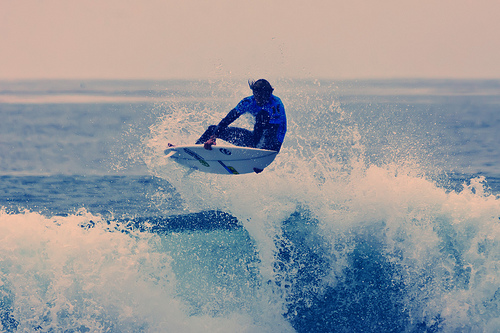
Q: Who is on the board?
A: A man.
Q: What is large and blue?
A: The wave.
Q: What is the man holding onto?
A: A surfboard.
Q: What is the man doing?
A: Surfing.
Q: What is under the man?
A: A surfboard.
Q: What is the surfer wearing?
A: A wet suit.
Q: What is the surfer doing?
A: Riding the waves.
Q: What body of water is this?
A: The ocean.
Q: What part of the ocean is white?
A: The waves.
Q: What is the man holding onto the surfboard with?
A: Two hands.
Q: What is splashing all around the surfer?
A: The waves.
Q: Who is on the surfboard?
A: A man.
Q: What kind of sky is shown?
A: Overcast.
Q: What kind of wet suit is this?
A: A blue one.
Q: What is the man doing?
A: Surfing.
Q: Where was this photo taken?
A: In the ocean.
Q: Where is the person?
A: On the board.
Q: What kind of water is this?
A: Salt water.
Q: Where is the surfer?
A: In the air.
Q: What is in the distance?
A: More ocean.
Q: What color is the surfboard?
A: White.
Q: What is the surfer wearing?
A: A wetsuit.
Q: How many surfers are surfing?
A: 1.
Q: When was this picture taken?
A: During the day.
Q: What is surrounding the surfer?
A: Ocean spray.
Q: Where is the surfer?
A: In the ocean.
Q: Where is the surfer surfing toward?
A: The shore.